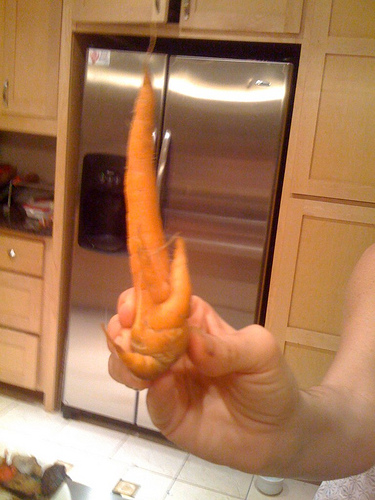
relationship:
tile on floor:
[0, 375, 320, 499] [51, 430, 167, 498]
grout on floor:
[0, 451, 78, 498] [75, 427, 186, 490]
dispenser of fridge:
[77, 151, 126, 256] [66, 36, 280, 460]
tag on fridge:
[81, 48, 117, 69] [73, 43, 295, 468]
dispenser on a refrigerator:
[77, 151, 126, 256] [56, 50, 298, 419]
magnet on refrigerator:
[73, 50, 116, 72] [41, 31, 286, 372]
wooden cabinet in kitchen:
[322, 4, 373, 53] [3, 7, 373, 438]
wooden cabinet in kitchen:
[314, 50, 366, 180] [3, 7, 373, 438]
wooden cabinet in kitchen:
[291, 198, 352, 330] [3, 7, 373, 438]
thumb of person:
[186, 325, 281, 380] [103, 238, 374, 498]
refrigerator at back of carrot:
[56, 50, 298, 419] [104, 64, 194, 379]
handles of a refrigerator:
[139, 128, 179, 255] [40, 37, 310, 392]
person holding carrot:
[103, 238, 374, 498] [99, 0, 191, 378]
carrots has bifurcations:
[116, 49, 192, 380] [150, 222, 204, 328]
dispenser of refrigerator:
[73, 148, 144, 258] [55, 41, 285, 488]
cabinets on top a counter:
[1, 3, 59, 122] [4, 179, 53, 249]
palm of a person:
[195, 369, 289, 462] [125, 75, 373, 498]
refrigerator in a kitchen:
[56, 50, 298, 419] [2, 0, 373, 498]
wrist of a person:
[259, 384, 334, 483] [103, 238, 374, 498]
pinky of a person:
[106, 348, 156, 395] [103, 238, 374, 498]